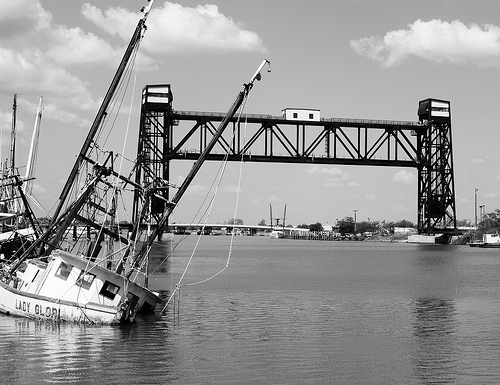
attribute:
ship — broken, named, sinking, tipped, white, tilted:
[5, 51, 266, 326]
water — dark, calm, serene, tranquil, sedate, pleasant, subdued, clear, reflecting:
[3, 220, 495, 373]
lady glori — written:
[14, 299, 68, 323]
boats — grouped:
[171, 230, 294, 237]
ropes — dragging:
[158, 95, 255, 318]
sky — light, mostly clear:
[11, 3, 493, 220]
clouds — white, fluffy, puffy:
[7, 0, 498, 147]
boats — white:
[5, 144, 152, 330]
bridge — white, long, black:
[128, 214, 319, 236]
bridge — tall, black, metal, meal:
[136, 83, 460, 246]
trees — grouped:
[315, 215, 412, 229]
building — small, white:
[279, 107, 326, 118]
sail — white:
[23, 98, 46, 206]